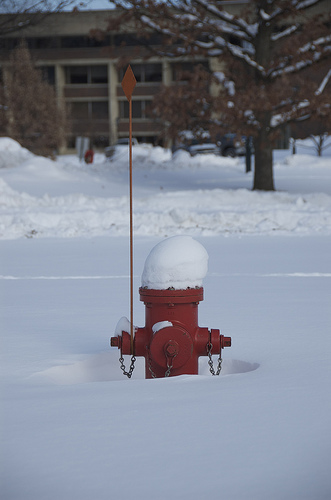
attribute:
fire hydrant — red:
[111, 236, 232, 376]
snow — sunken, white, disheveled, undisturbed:
[139, 234, 211, 288]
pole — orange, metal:
[119, 101, 148, 351]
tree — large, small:
[112, 0, 330, 199]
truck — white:
[194, 120, 243, 170]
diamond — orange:
[108, 58, 144, 101]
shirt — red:
[82, 148, 97, 166]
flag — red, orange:
[110, 58, 142, 341]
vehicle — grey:
[104, 139, 149, 157]